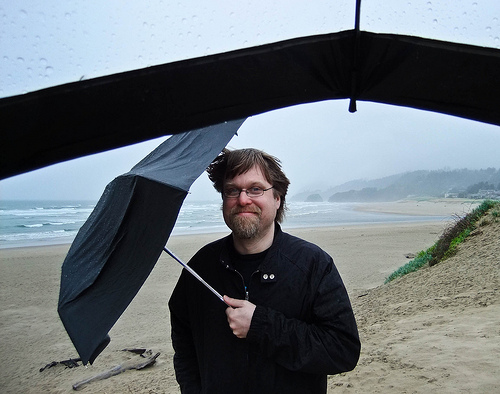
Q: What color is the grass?
A: Green.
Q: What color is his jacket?
A: Black.